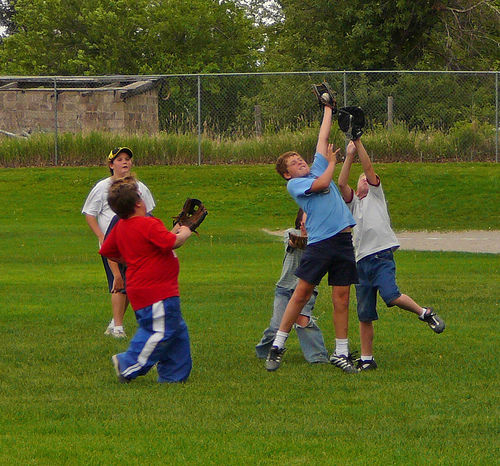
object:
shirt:
[82, 177, 157, 250]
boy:
[80, 144, 156, 338]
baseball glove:
[171, 197, 209, 239]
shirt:
[342, 174, 401, 264]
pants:
[116, 296, 192, 385]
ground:
[359, 137, 427, 202]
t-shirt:
[97, 217, 180, 311]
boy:
[98, 175, 208, 385]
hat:
[108, 147, 134, 163]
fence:
[0, 67, 498, 166]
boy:
[263, 105, 359, 374]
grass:
[3, 388, 498, 464]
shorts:
[294, 231, 360, 286]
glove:
[338, 106, 368, 141]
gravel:
[402, 229, 499, 253]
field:
[2, 165, 481, 464]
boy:
[255, 208, 331, 365]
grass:
[0, 115, 500, 164]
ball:
[321, 92, 330, 102]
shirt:
[287, 151, 358, 246]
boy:
[338, 135, 446, 375]